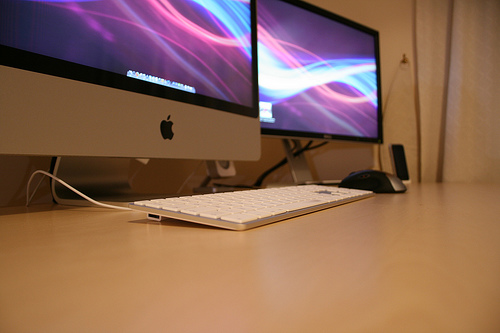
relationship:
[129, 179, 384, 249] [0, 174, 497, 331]
keyboard on table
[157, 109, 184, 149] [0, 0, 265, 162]
symbol on monitor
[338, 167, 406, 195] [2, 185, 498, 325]
mouse on table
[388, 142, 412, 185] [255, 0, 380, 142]
speaker next to monitor